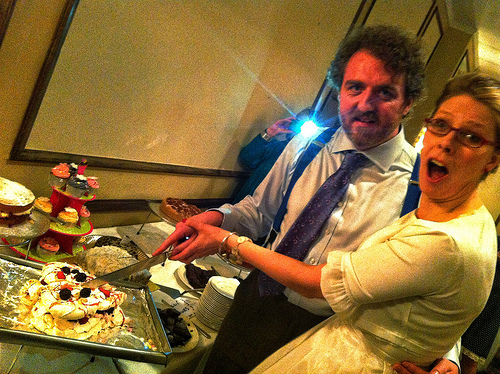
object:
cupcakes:
[0, 154, 95, 264]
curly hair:
[382, 24, 433, 101]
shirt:
[200, 122, 422, 317]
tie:
[255, 150, 370, 299]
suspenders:
[264, 124, 423, 253]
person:
[233, 108, 329, 205]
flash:
[144, 0, 277, 119]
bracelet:
[218, 232, 255, 259]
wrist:
[221, 233, 245, 263]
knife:
[81, 250, 174, 289]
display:
[132, 190, 230, 264]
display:
[0, 157, 100, 263]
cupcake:
[34, 197, 54, 214]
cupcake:
[50, 158, 100, 235]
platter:
[0, 157, 98, 263]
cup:
[193, 276, 242, 332]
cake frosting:
[15, 261, 134, 347]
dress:
[248, 204, 500, 374]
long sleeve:
[320, 229, 458, 316]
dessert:
[11, 261, 131, 342]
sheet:
[0, 248, 173, 369]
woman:
[152, 25, 499, 373]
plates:
[193, 276, 239, 332]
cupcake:
[36, 236, 60, 260]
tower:
[0, 155, 103, 262]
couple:
[152, 23, 500, 373]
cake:
[0, 177, 37, 228]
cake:
[72, 245, 153, 290]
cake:
[159, 195, 202, 223]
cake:
[184, 258, 222, 289]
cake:
[157, 306, 192, 347]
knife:
[162, 294, 213, 339]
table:
[0, 175, 250, 371]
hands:
[152, 210, 231, 266]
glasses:
[425, 116, 500, 152]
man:
[151, 23, 429, 373]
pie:
[160, 196, 202, 222]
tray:
[148, 202, 177, 227]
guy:
[152, 21, 427, 373]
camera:
[288, 117, 324, 134]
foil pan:
[1, 252, 176, 366]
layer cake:
[0, 176, 36, 228]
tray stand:
[0, 238, 88, 263]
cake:
[18, 260, 133, 342]